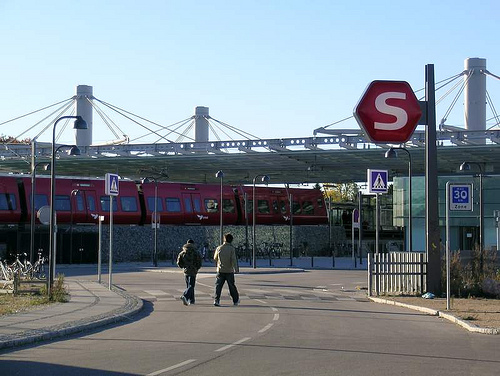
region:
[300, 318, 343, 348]
part of a road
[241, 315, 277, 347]
white lines on the road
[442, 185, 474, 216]
part of a road sign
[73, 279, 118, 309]
part of a walking path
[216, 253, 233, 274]
part of a jacket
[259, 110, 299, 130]
part of the sky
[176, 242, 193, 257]
part of a hood on a jacket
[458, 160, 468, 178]
part of a street lamp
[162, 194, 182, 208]
a window on a train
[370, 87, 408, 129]
part of a red banner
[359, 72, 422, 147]
Red and white sign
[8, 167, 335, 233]
Red colored light rail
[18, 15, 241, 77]
Clear blue sky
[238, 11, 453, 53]
Clear blue sky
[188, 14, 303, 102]
Clear blue sky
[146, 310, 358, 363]
gray pavement with white stripe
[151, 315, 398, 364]
gray street with white stripe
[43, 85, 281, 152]
Gray supports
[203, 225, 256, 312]
Man walking and wearing tan jacket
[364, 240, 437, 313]
Gray fence at light rail station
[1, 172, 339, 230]
a red train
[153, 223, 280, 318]
two people walking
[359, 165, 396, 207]
a blue and white sign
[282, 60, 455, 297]
a large red and white sign on a pole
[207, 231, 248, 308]
a person wearing a tan jacket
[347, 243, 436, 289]
a white fence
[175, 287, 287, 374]
white lines painted on a road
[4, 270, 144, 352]
a cement sidewalk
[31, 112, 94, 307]
two tall street lamps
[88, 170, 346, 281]
a row of street lamps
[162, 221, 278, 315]
Two people walk on the street.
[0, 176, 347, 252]
A train is in the background.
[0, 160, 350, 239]
The train is red.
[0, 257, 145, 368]
A sidewalk leads to the train.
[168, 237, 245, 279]
The men are wearing coats.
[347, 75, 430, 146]
The sign has a large S on it.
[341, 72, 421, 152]
The sign is red.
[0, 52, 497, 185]
A bridge is above the train.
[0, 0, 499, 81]
The sky is blue.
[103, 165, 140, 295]
A street sign is on the sidewalk.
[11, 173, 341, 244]
one train is seen.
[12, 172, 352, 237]
Train is red color.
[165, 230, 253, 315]
Two person are walking in the road.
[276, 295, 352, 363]
road is grey color.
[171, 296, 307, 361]
white lines on road.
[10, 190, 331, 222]
windows in sides of the train.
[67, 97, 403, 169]
bridge is grey color.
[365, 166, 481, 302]
Boards are in sidewalk.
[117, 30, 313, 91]
Sky is blue color.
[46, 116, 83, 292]
Lamp post is grey color.